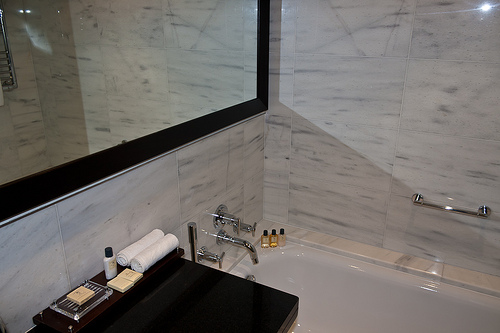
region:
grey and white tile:
[296, 0, 433, 95]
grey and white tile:
[399, 98, 496, 183]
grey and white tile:
[294, 99, 408, 188]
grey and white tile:
[162, 129, 259, 216]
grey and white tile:
[63, 165, 173, 282]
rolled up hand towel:
[134, 228, 184, 282]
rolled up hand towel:
[105, 218, 164, 262]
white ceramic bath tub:
[257, 235, 422, 330]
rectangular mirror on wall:
[2, 0, 309, 203]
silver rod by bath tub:
[396, 182, 496, 239]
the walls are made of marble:
[334, 36, 449, 188]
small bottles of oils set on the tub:
[257, 216, 299, 249]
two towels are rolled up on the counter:
[109, 213, 177, 275]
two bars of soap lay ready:
[108, 263, 156, 294]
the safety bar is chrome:
[401, 172, 498, 234]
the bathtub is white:
[281, 269, 381, 330]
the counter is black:
[146, 300, 215, 331]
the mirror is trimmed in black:
[31, 110, 224, 160]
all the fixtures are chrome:
[203, 207, 263, 272]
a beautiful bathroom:
[38, 6, 483, 331]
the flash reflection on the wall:
[416, 0, 498, 22]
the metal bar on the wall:
[411, 191, 491, 219]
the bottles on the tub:
[259, 228, 286, 247]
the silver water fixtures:
[195, 200, 258, 269]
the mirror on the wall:
[0, 0, 270, 232]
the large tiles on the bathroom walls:
[0, 1, 498, 331]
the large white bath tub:
[225, 231, 498, 331]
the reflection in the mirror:
[0, 0, 257, 182]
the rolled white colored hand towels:
[113, 227, 178, 272]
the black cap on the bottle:
[103, 245, 113, 257]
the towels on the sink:
[113, 228, 180, 272]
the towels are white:
[112, 224, 175, 278]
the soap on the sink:
[108, 270, 141, 289]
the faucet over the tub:
[210, 225, 280, 274]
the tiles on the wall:
[301, 8, 498, 250]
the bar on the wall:
[410, 190, 492, 232]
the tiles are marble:
[298, 11, 493, 164]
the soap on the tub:
[253, 223, 295, 249]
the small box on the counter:
[67, 285, 94, 302]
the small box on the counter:
[107, 277, 132, 291]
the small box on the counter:
[116, 267, 142, 284]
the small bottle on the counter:
[103, 246, 116, 278]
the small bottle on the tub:
[260, 228, 270, 246]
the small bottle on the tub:
[269, 229, 278, 246]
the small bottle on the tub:
[280, 228, 286, 248]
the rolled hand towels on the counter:
[116, 227, 179, 272]